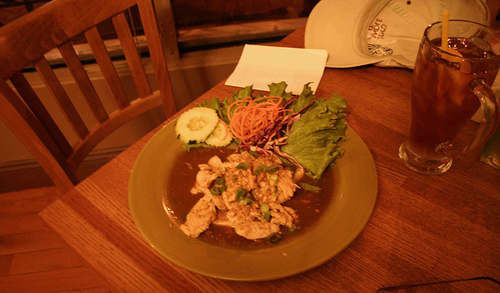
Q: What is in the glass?
A: Tea.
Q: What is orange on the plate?
A: Carrots.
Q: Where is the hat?
A: Top right.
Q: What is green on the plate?
A: Lettuce.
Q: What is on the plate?
A: Food.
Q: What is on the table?
A: A glass.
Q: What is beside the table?
A: Chair.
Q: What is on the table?
A: Hat.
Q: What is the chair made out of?
A: Wood.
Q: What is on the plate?
A: Lettuce.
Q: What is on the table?
A: Paper.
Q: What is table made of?
A: Wood.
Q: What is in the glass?
A: Straw.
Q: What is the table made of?
A: Wood.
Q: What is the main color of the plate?
A: Green.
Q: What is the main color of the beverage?
A: Brown.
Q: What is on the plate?
A: Salad.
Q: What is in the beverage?
A: Straw.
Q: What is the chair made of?
A: Wood.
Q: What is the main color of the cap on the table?
A: White.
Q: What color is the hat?
A: White.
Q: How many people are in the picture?
A: 0.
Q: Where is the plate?
A: On the table.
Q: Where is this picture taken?
A: In a kitchen.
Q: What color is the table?
A: Brown.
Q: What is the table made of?
A: Wood.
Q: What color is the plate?
A: Green.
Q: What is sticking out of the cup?
A: A straw.